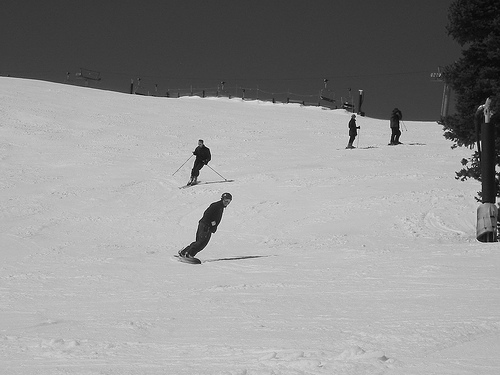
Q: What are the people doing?
A: Skiing and snowboarding.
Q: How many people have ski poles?
A: 3.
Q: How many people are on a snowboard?
A: 1.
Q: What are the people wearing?
A: Cold weather gear.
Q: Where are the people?
A: On a ski hill.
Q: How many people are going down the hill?
A: 4.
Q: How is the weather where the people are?
A: Cold.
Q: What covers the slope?
A: Snow.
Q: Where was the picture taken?
A: On a ski slope.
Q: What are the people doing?
A: Skiing and snowboarding.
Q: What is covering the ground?
A: Snow.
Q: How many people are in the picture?
A: 4.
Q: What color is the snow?
A: White.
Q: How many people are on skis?
A: 3.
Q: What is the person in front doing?
A: Snowboarding.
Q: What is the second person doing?
A: Skiing.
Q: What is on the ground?
A: Snow.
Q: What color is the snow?
A: White.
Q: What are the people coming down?
A: Ski hill.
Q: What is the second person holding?
A: Poles.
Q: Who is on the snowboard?
A: A man.